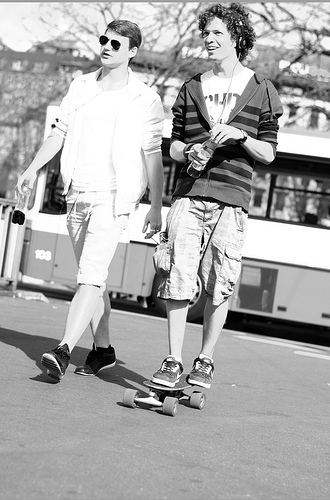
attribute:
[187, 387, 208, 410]
wheel — large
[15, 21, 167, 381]
man — walking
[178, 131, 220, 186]
bottle — drink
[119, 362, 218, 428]
skateboard —  skateboard's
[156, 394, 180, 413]
wheel —  the right,  the  front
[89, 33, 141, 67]
glasses — black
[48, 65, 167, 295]
clothes — white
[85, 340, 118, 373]
left foot — boy's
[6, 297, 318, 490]
street — concrete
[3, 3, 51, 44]
sky — clear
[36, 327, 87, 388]
shoe — black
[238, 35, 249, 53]
headphones — dark, colored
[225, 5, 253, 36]
hair — curly